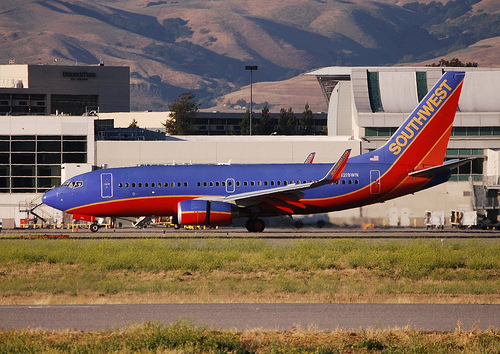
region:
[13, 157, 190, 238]
purple airplane on land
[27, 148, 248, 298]
purple airplane on land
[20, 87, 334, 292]
purple airplane on land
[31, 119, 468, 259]
the plane is blue and red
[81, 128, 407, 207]
the plane is blue and red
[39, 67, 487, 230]
red and blue airplane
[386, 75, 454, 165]
southwest written on tail in yellow leters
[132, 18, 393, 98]
huge mountain in backdrop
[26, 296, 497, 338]
black tarmac of runway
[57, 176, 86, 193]
window to pilot's cockpit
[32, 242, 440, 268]
strip of overgrown weeds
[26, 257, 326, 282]
bar patch of dirt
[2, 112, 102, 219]
concrete building with multiple windows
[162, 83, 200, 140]
tall tree with green leaves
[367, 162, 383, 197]
emergency exit on plane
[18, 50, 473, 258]
Southwest airplane sitting on runway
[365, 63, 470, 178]
Name of airline in yellow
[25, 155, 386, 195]
Passenger windows on left side of plane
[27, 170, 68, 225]
Nose of airplane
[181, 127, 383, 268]
Left wing of airplane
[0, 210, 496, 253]
Runway plane is sitting on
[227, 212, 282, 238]
Rear wheel of airplane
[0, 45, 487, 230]
White building on side of airplane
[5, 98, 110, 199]
Windows in white building on side of airplane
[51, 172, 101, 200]
cockpit of airplane